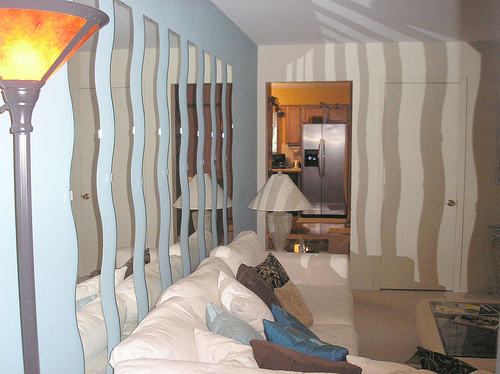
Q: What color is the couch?
A: White.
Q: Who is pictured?
A: No one.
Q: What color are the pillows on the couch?
A: Blue, white, black and brown.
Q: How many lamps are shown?
A: Two.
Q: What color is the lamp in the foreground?
A: Orange and black.